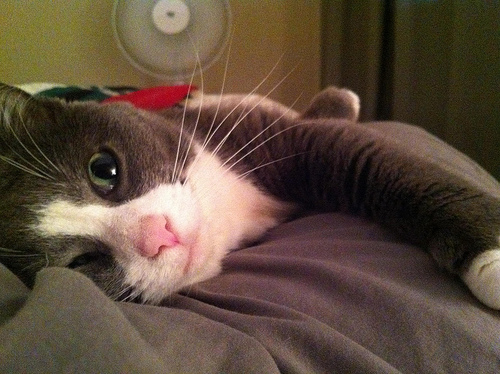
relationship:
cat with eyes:
[0, 82, 499, 316] [77, 133, 136, 188]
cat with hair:
[0, 82, 499, 316] [172, 88, 311, 222]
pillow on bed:
[12, 82, 296, 118] [1, 83, 498, 373]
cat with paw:
[0, 82, 499, 316] [466, 249, 499, 312]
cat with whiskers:
[0, 82, 499, 316] [178, 61, 316, 187]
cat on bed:
[11, 64, 475, 320] [19, 35, 435, 361]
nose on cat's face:
[123, 203, 185, 259] [34, 67, 287, 324]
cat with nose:
[0, 82, 499, 316] [128, 217, 177, 260]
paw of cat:
[418, 197, 497, 318] [20, 105, 358, 348]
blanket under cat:
[96, 105, 475, 370] [0, 82, 499, 316]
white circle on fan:
[150, 1, 189, 34] [111, 1, 238, 80]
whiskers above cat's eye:
[18, 122, 61, 193] [74, 143, 161, 333]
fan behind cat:
[104, 2, 246, 102] [1, 63, 498, 338]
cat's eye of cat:
[69, 142, 133, 270] [0, 82, 499, 316]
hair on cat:
[172, 28, 312, 223] [11, 64, 475, 320]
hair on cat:
[172, 28, 312, 223] [0, 82, 499, 316]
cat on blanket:
[0, 82, 499, 316] [188, 55, 446, 365]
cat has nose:
[0, 82, 499, 316] [126, 212, 180, 259]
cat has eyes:
[0, 82, 499, 316] [64, 146, 124, 266]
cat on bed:
[11, 64, 475, 320] [1, 83, 498, 373]